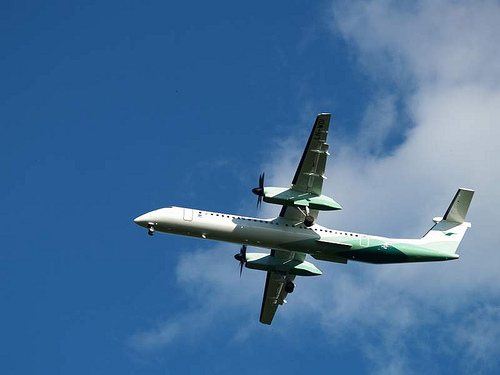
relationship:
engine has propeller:
[261, 186, 345, 211] [252, 172, 267, 207]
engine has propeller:
[244, 253, 323, 277] [234, 244, 250, 278]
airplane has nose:
[132, 113, 477, 326] [132, 208, 164, 235]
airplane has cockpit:
[132, 113, 477, 326] [159, 204, 177, 212]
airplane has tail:
[132, 113, 477, 326] [417, 186, 476, 254]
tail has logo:
[417, 186, 476, 254] [436, 229, 461, 238]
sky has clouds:
[2, 3, 499, 372] [123, 1, 500, 372]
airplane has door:
[132, 113, 477, 326] [182, 207, 194, 222]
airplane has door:
[132, 113, 477, 326] [358, 234, 371, 247]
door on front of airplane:
[182, 207, 194, 222] [132, 113, 477, 326]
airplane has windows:
[132, 113, 477, 326] [192, 210, 361, 239]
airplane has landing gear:
[132, 113, 477, 326] [147, 207, 315, 291]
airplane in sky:
[132, 113, 477, 326] [2, 3, 499, 372]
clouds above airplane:
[123, 1, 500, 372] [132, 113, 477, 326]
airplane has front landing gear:
[132, 113, 477, 326] [146, 222, 156, 236]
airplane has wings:
[132, 113, 477, 326] [258, 111, 333, 327]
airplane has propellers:
[132, 113, 477, 326] [234, 172, 265, 275]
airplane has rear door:
[132, 113, 477, 326] [358, 234, 371, 247]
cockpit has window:
[159, 204, 177, 212] [165, 205, 175, 209]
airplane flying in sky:
[132, 113, 477, 326] [2, 3, 499, 372]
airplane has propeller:
[132, 113, 477, 326] [252, 172, 267, 207]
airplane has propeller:
[132, 113, 477, 326] [234, 244, 250, 278]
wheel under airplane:
[302, 216, 315, 227] [132, 113, 477, 326]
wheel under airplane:
[284, 282, 295, 292] [132, 113, 477, 326]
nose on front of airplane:
[132, 208, 164, 235] [132, 113, 477, 326]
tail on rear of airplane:
[417, 186, 476, 254] [132, 113, 477, 326]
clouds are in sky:
[123, 1, 500, 372] [2, 3, 499, 372]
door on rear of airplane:
[358, 234, 371, 247] [132, 113, 477, 326]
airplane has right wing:
[132, 113, 477, 326] [258, 249, 307, 325]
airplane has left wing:
[132, 113, 477, 326] [276, 111, 332, 224]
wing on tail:
[440, 187, 475, 225] [417, 186, 476, 254]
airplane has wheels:
[132, 113, 477, 326] [147, 215, 315, 293]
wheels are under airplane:
[147, 215, 315, 293] [132, 113, 477, 326]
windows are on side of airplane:
[192, 210, 361, 239] [132, 113, 477, 326]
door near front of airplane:
[182, 207, 194, 222] [132, 113, 477, 326]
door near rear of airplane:
[358, 234, 371, 247] [132, 113, 477, 326]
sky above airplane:
[2, 3, 499, 372] [132, 113, 477, 326]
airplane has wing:
[132, 113, 477, 326] [258, 249, 307, 325]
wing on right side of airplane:
[258, 249, 307, 325] [132, 113, 477, 326]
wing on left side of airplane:
[276, 111, 332, 224] [132, 113, 477, 326]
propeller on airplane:
[252, 172, 267, 207] [132, 113, 477, 326]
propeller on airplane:
[234, 244, 250, 278] [132, 113, 477, 326]